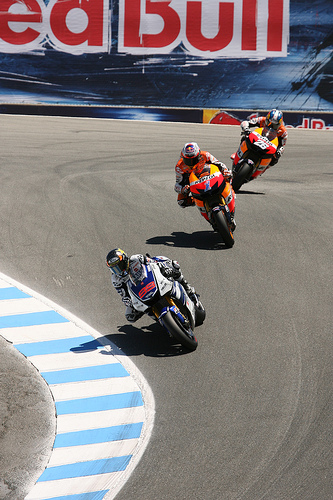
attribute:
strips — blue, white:
[47, 321, 127, 467]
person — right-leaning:
[238, 109, 287, 158]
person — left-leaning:
[172, 137, 239, 248]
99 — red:
[137, 280, 154, 298]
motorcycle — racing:
[229, 103, 289, 184]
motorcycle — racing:
[165, 137, 243, 245]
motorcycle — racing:
[95, 241, 212, 330]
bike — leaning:
[125, 253, 205, 350]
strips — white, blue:
[0, 271, 156, 498]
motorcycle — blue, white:
[128, 250, 209, 353]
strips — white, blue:
[23, 357, 176, 496]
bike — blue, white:
[154, 131, 253, 246]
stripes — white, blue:
[17, 309, 111, 427]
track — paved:
[156, 308, 326, 456]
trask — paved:
[41, 165, 156, 228]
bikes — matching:
[170, 86, 301, 252]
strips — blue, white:
[3, 307, 70, 328]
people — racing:
[98, 91, 290, 354]